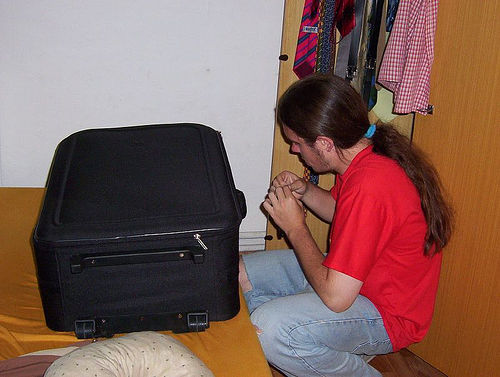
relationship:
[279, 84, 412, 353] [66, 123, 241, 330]
man with luggage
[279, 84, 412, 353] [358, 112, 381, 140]
man wearing band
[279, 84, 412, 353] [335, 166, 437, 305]
man wearing shirt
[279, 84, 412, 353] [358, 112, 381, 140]
man with band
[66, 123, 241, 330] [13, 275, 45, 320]
luggage on table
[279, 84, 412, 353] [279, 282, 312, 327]
man wearing jeans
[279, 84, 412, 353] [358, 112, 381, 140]
man has band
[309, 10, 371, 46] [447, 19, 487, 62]
ties on door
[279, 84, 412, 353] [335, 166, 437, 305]
man with shirt